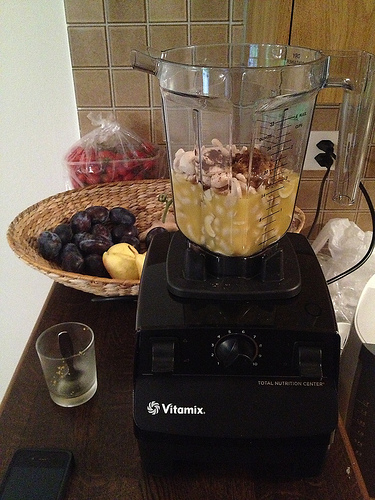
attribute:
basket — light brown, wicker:
[8, 178, 306, 295]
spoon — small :
[56, 330, 84, 381]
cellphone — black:
[6, 449, 70, 497]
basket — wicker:
[6, 177, 179, 291]